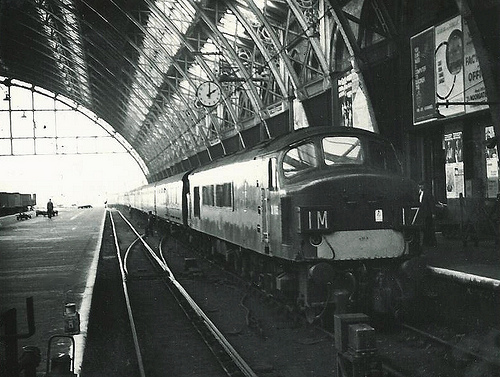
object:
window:
[201, 184, 214, 206]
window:
[215, 183, 232, 206]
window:
[369, 136, 403, 173]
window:
[282, 142, 318, 177]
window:
[322, 135, 365, 165]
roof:
[0, 1, 358, 184]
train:
[106, 125, 428, 323]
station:
[0, 0, 499, 375]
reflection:
[321, 135, 363, 167]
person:
[46, 197, 54, 218]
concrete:
[0, 206, 107, 376]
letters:
[316, 211, 328, 229]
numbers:
[402, 206, 407, 224]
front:
[280, 130, 422, 323]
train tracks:
[109, 209, 147, 375]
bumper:
[316, 227, 408, 259]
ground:
[0, 206, 499, 375]